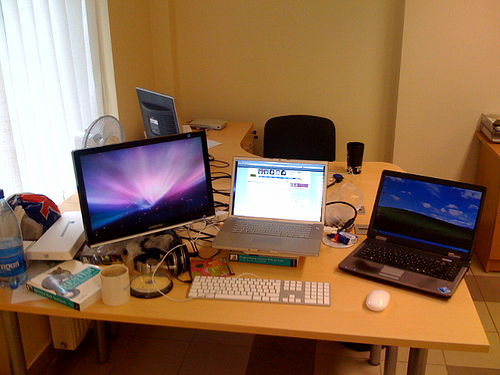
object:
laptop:
[212, 156, 329, 258]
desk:
[0, 121, 490, 353]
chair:
[262, 114, 336, 161]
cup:
[346, 142, 364, 175]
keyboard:
[187, 275, 330, 305]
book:
[25, 260, 104, 312]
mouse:
[366, 289, 391, 311]